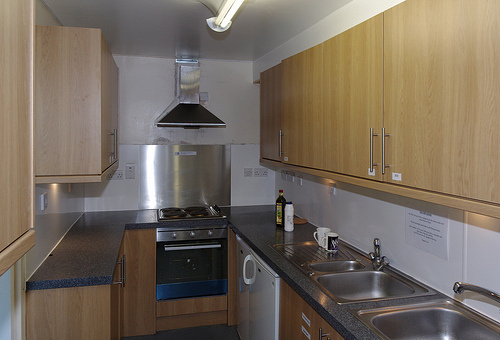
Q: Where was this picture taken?
A: Kitchen.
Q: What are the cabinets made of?
A: Wood.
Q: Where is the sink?
A: On the right.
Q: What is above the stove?
A: Hood.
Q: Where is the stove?
A: Below the hood.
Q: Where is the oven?
A: Below the stove.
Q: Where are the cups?
A: Beside the sink.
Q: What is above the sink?
A: A sign.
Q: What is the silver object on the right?
A: A sink.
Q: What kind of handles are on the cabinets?
A: Metal.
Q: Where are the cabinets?
A: In a kitchen.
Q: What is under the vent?
A: A stove and oven combination.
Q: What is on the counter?
A: Olive oil.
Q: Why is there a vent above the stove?
A: To absorb the smoke.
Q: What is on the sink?
A: The mugs.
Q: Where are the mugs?
A: On the sink.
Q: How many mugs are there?
A: 2.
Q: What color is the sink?
A: Silver.